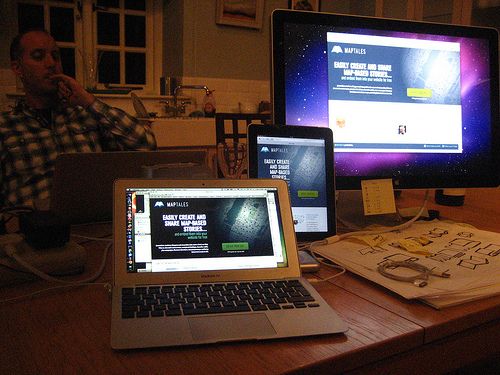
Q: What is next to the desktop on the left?
A: Laptop.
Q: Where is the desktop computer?
A: Desk.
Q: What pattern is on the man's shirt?
A: Plaid.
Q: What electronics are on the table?
A: Laptop.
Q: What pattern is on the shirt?
A: Plaid.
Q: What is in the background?
A: Tv.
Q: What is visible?
A: A computer.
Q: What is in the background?
A: Window.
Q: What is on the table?
A: Papers.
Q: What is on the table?
A: Cords.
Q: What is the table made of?
A: Wood.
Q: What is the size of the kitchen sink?
A: Large.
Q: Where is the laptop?
A: On the table.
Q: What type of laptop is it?
A: Macbook Air.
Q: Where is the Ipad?
A: Next to the computer.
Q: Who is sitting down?
A: The man.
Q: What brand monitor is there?
A: Apple.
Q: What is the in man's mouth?
A: His finger.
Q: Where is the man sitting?
A: In the kitchen.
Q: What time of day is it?
A: The night.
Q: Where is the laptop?
A: On the table.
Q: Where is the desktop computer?
A: On the desk.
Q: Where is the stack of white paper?
A: On the desk.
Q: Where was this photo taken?
A: In the kitchen.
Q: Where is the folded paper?
A: On top of the table.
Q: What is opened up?
A: The laptop.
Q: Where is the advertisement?
A: On the computer screen.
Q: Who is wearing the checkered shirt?
A: The man.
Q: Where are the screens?
A: On the table.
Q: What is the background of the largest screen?
A: Stars.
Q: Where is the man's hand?
A: On his mouth.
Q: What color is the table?
A: Brown.